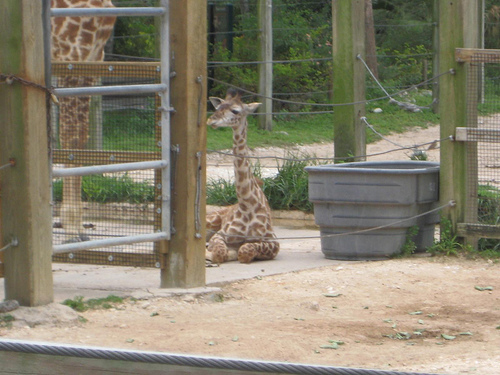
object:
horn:
[230, 91, 240, 101]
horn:
[221, 83, 234, 100]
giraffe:
[206, 86, 281, 269]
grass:
[0, 295, 126, 338]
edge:
[0, 342, 395, 375]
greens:
[311, 286, 497, 352]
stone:
[301, 300, 320, 311]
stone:
[488, 291, 494, 296]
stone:
[311, 300, 321, 314]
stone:
[141, 302, 148, 309]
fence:
[0, 0, 500, 309]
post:
[154, 0, 213, 287]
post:
[0, 0, 65, 307]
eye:
[231, 108, 239, 115]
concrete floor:
[0, 218, 323, 322]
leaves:
[273, 165, 309, 210]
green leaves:
[210, 0, 499, 111]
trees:
[320, 0, 500, 94]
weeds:
[401, 181, 500, 259]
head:
[207, 86, 264, 129]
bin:
[303, 159, 440, 261]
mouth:
[207, 122, 219, 129]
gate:
[29, 0, 211, 295]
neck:
[229, 127, 265, 209]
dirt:
[0, 112, 500, 375]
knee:
[207, 240, 228, 261]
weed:
[60, 291, 136, 312]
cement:
[0, 213, 344, 318]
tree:
[206, 0, 332, 110]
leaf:
[277, 65, 284, 70]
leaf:
[243, 68, 249, 74]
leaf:
[240, 41, 246, 43]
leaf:
[244, 20, 247, 22]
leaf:
[276, 63, 279, 68]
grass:
[47, 74, 500, 264]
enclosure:
[0, 0, 500, 375]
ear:
[243, 101, 263, 114]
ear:
[209, 96, 225, 109]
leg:
[209, 228, 230, 265]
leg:
[237, 237, 278, 263]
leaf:
[232, 334, 239, 342]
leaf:
[208, 340, 214, 346]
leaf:
[320, 339, 345, 349]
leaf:
[441, 333, 458, 340]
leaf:
[408, 311, 422, 315]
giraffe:
[38, 0, 123, 247]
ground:
[0, 90, 500, 375]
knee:
[236, 243, 257, 263]